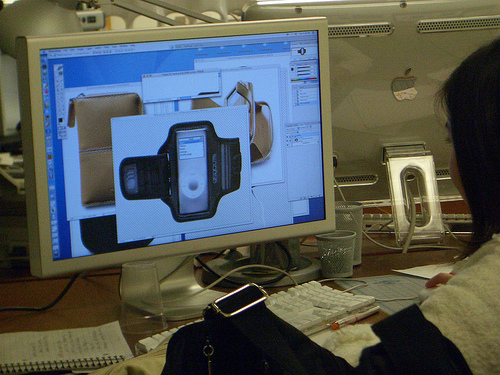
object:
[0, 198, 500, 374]
desk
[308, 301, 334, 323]
key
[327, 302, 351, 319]
key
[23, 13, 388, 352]
computer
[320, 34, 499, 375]
lady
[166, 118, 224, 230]
ipod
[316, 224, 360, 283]
cups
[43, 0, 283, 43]
lamp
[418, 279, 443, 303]
mouse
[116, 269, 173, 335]
cup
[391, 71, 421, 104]
logo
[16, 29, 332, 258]
monitor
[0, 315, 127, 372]
notebook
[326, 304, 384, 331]
pen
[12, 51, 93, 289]
sidebar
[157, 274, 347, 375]
bag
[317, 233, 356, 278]
paper clip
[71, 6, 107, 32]
plug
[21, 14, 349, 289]
frame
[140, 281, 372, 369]
keyboard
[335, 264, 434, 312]
mousepad